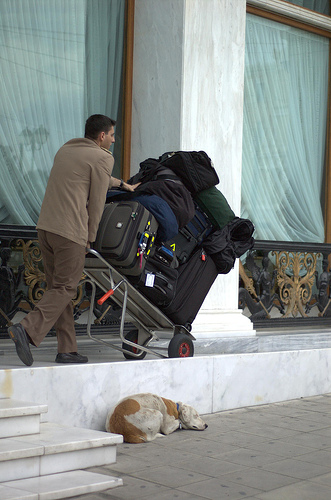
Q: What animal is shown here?
A: Dog.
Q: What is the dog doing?
A: Sleeping.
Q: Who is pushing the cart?
A: The man.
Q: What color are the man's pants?
A: Brown.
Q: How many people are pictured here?
A: One.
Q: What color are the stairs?
A: White.